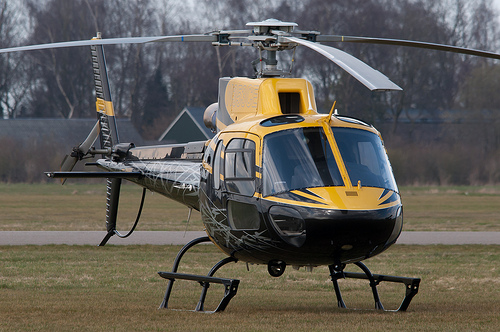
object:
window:
[233, 149, 257, 181]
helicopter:
[0, 16, 499, 314]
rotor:
[274, 30, 402, 94]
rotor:
[314, 30, 499, 63]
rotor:
[0, 33, 218, 55]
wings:
[0, 18, 499, 92]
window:
[324, 126, 404, 197]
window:
[259, 126, 344, 199]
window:
[224, 177, 256, 200]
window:
[210, 140, 224, 191]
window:
[225, 199, 259, 232]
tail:
[86, 32, 124, 248]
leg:
[151, 235, 242, 315]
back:
[96, 141, 210, 214]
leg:
[326, 258, 419, 314]